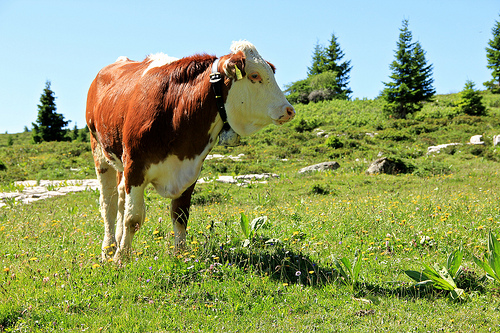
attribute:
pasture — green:
[5, 183, 496, 314]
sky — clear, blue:
[2, 2, 498, 121]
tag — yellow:
[226, 61, 255, 84]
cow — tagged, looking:
[83, 35, 299, 270]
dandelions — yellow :
[0, 150, 499, 331]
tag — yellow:
[231, 64, 247, 89]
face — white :
[212, 25, 313, 170]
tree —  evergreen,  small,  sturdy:
[31, 69, 76, 143]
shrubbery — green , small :
[275, 33, 334, 138]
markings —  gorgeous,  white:
[122, 193, 146, 266]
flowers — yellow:
[0, 225, 205, 275]